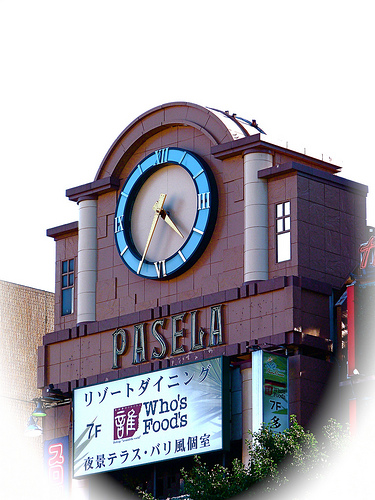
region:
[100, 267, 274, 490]
This is a sign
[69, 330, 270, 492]
This is in asia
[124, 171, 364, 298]
This is a clock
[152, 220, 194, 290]
The hand is gold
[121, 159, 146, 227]
The border is blue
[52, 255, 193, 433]
These are red bricks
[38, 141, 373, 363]
This is a building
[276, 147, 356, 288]
This is a window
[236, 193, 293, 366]
The window is skinny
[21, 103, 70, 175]
this is the sky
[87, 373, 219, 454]
this is a notice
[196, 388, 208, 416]
the notice is white in color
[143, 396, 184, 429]
thiu\s is a writing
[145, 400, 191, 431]
the writing is in black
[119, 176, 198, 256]
this is a clock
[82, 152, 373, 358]
this is a building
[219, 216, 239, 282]
this is the wall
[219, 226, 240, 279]
the wall is brown in color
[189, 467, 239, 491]
this is a tree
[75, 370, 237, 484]
This is japanese language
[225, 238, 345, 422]
This is a tower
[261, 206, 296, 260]
The window is skinny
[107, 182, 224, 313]
This is a clock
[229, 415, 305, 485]
This is an old tree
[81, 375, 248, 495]
The sign is a rectangle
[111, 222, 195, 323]
The hand is gold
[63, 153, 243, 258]
The boarder is blue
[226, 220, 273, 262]
This is a column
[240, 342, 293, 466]
The sign is green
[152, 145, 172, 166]
number on a clock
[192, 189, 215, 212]
number on a clock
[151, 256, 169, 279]
number on a clock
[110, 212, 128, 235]
number on a clock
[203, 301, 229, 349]
large letter on a building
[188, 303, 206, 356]
large letter on a building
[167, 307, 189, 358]
large letter on a building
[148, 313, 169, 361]
large letter on a building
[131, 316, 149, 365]
large letter on a building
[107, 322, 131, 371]
large letter on a building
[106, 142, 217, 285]
blue clock on a building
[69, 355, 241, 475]
chinese writing on a sign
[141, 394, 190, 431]
who's food name of shore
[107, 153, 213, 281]
clock that says 4:30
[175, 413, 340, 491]
green plant in the distance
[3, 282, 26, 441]
brick wall on a building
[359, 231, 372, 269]
neon light from another business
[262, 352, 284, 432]
7F sign on a building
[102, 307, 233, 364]
PASELA writing on a building